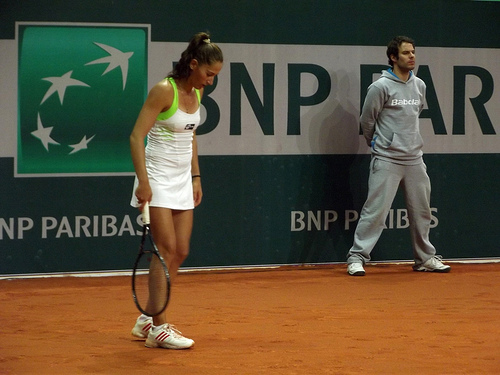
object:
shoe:
[145, 323, 196, 348]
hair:
[165, 33, 223, 78]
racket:
[130, 199, 170, 316]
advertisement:
[0, 20, 498, 275]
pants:
[346, 156, 439, 266]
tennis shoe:
[129, 312, 155, 338]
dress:
[130, 76, 207, 210]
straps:
[157, 74, 202, 134]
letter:
[16, 213, 34, 241]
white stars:
[80, 41, 134, 93]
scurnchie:
[199, 38, 213, 46]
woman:
[131, 33, 224, 351]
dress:
[127, 75, 202, 212]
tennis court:
[1, 0, 498, 373]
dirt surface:
[0, 262, 500, 374]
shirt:
[356, 71, 426, 165]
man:
[344, 37, 451, 273]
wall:
[0, 46, 497, 276]